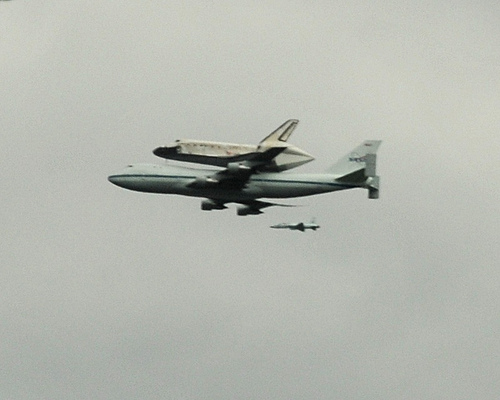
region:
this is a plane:
[76, 91, 391, 253]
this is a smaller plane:
[254, 208, 333, 262]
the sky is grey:
[74, 51, 153, 111]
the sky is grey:
[278, 268, 372, 340]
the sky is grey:
[171, 19, 301, 93]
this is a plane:
[111, 118, 398, 218]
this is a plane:
[224, 203, 381, 278]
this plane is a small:
[268, 203, 336, 243]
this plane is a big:
[95, 129, 406, 227]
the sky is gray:
[360, 249, 428, 351]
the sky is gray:
[40, 228, 154, 332]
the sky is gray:
[40, 21, 171, 83]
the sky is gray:
[165, 272, 329, 376]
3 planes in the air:
[100, 114, 390, 244]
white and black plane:
[151, 119, 312, 172]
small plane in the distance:
[268, 208, 315, 238]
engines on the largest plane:
[180, 160, 267, 219]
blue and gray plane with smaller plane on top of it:
[98, 127, 380, 211]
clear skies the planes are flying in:
[4, 6, 498, 396]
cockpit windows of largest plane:
[124, 163, 131, 168]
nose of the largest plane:
[106, 173, 128, 188]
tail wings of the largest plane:
[331, 130, 385, 199]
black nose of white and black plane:
[154, 142, 173, 158]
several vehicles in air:
[106, 114, 384, 234]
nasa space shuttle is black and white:
[151, 117, 315, 170]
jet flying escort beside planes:
[270, 217, 322, 234]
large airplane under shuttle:
[103, 137, 383, 217]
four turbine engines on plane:
[191, 160, 257, 216]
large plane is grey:
[106, 139, 388, 215]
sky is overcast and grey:
[1, 1, 499, 398]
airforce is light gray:
[270, 213, 321, 231]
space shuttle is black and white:
[152, 120, 315, 167]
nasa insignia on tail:
[344, 140, 373, 165]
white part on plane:
[258, 116, 302, 147]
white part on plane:
[338, 132, 400, 182]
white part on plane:
[262, 138, 287, 158]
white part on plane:
[161, 133, 239, 160]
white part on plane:
[282, 136, 314, 180]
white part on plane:
[104, 159, 201, 203]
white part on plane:
[265, 162, 346, 206]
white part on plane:
[275, 212, 330, 233]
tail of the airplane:
[355, 141, 395, 197]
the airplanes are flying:
[95, 123, 443, 214]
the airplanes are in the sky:
[108, 117, 393, 232]